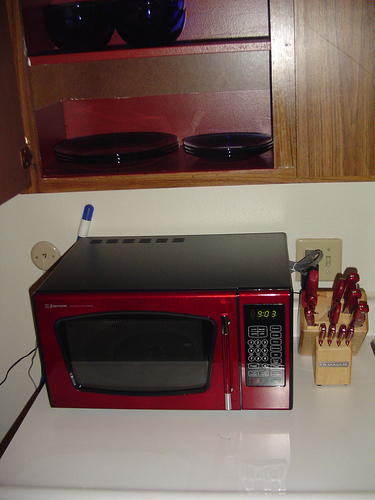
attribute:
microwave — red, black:
[30, 235, 293, 411]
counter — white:
[2, 339, 371, 496]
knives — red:
[305, 267, 367, 345]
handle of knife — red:
[351, 306, 369, 329]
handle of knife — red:
[332, 302, 342, 329]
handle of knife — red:
[332, 275, 345, 308]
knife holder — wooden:
[301, 291, 368, 386]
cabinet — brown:
[0, 1, 373, 194]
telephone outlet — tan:
[31, 241, 59, 271]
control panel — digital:
[248, 323, 282, 379]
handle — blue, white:
[78, 206, 92, 242]